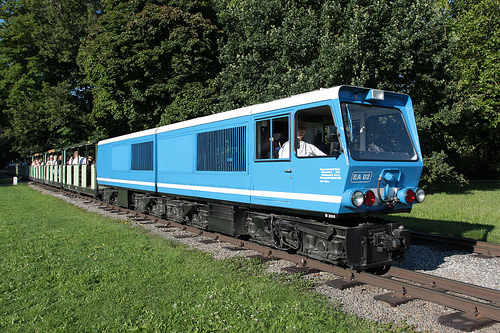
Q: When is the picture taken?
A: Daytime.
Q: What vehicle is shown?
A: A train.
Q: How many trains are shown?
A: 1.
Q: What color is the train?
A: Blue.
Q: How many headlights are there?
A: 4.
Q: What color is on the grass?
A: Green.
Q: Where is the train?
A: On the track.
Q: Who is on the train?
A: The conductor and riders.